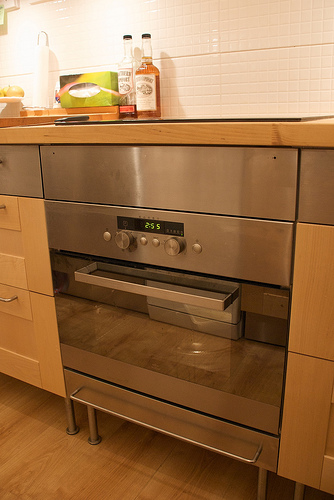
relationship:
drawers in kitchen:
[0, 182, 52, 383] [0, 1, 323, 443]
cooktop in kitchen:
[51, 112, 331, 123] [1, 1, 331, 498]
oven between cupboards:
[42, 198, 294, 475] [0, 195, 67, 403]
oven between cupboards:
[42, 198, 294, 475] [272, 221, 333, 495]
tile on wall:
[219, 54, 276, 115] [0, 0, 334, 114]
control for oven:
[161, 237, 182, 256] [41, 196, 299, 436]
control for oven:
[109, 228, 136, 248] [41, 196, 299, 436]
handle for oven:
[71, 258, 240, 312] [46, 249, 291, 437]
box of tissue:
[59, 71, 120, 107] [54, 70, 122, 109]